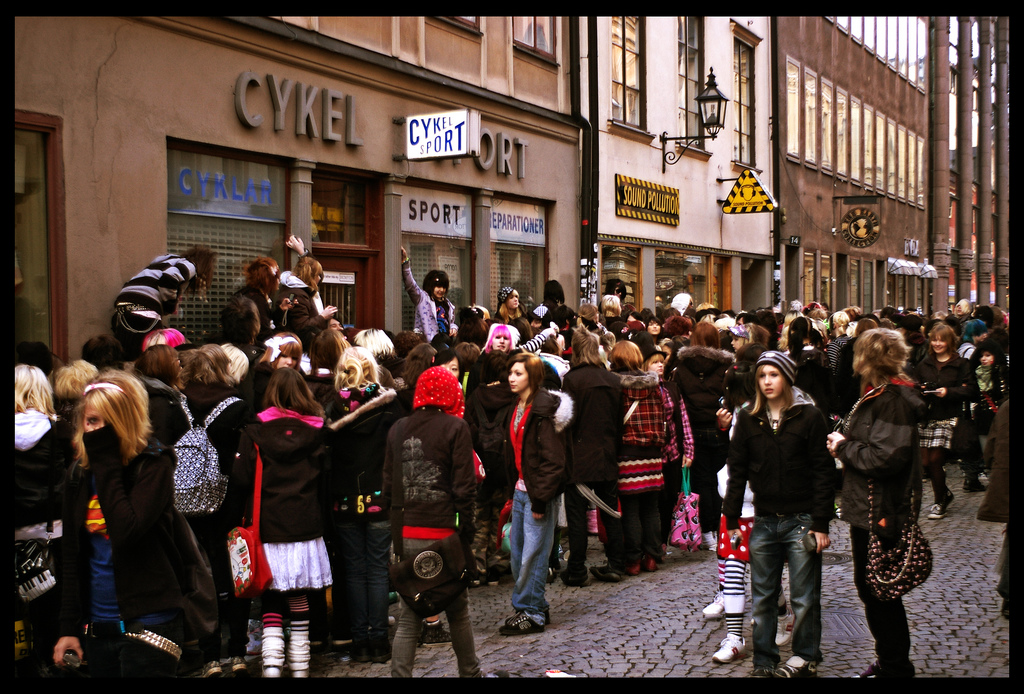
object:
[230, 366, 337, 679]
person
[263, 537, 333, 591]
skirt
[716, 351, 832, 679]
person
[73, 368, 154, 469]
hair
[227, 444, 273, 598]
bag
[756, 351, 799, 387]
hat